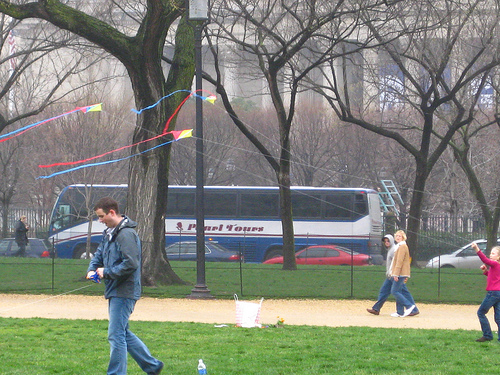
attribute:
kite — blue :
[35, 125, 200, 200]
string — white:
[1, 272, 105, 317]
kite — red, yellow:
[1, 90, 106, 147]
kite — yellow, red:
[128, 77, 222, 121]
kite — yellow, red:
[34, 126, 211, 178]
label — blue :
[198, 365, 203, 368]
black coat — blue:
[85, 187, 158, 372]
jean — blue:
[101, 295, 163, 373]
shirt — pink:
[391, 237, 420, 279]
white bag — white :
[193, 269, 289, 347]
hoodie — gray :
[388, 238, 411, 284]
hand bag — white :
[227, 286, 269, 339]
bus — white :
[48, 178, 390, 260]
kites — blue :
[77, 90, 201, 172]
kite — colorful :
[39, 130, 194, 180]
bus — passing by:
[51, 183, 381, 264]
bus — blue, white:
[56, 178, 301, 257]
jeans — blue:
[475, 290, 497, 340]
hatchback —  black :
[6, 231, 58, 256]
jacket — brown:
[394, 237, 414, 280]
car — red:
[261, 242, 381, 272]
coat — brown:
[387, 242, 420, 282]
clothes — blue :
[89, 213, 169, 368]